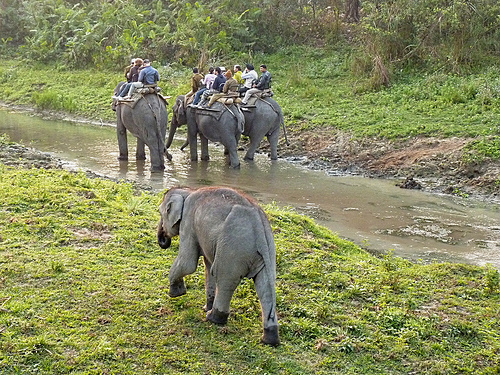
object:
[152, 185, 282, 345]
elephant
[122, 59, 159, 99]
man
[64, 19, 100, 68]
bush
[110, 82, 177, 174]
elephants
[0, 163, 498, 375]
grass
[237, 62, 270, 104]
people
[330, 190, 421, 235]
lush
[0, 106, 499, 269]
river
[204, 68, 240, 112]
tourists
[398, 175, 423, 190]
rocks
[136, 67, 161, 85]
shirt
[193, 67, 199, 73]
hair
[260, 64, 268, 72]
cap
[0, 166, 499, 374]
plants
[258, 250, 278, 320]
tail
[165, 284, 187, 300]
feet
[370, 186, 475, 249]
muddy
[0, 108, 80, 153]
shore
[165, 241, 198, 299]
leg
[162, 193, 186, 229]
ear